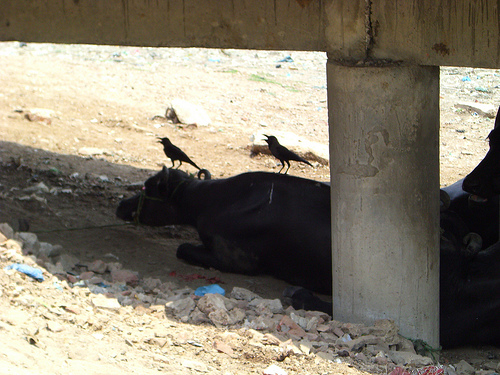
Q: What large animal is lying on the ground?
A: Cow.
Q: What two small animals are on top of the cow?
A: Black birds.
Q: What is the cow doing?
A: Lying down.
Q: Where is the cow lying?
A: Under a bridge.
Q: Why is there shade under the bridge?
A: The sun is shining.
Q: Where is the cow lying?
A: In the shade.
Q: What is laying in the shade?
A: A black cow.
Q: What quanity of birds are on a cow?
A: Two.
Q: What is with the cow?
A: Birds.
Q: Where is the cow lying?
A: On rocks.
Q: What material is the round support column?
A: Cement.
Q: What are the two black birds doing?
A: Singing.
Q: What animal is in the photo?
A: A cow.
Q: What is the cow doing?
A: Laying down.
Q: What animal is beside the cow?
A: The bird.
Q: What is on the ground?
A: Rocks.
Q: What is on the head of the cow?
A: Horns.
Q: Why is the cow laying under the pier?
A: For shade.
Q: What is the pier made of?
A: Concrete.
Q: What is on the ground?
A: Rubble.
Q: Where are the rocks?
A: On the ground.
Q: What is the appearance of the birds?
A: Sillouhettes.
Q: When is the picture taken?
A: Daytime.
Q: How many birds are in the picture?
A: Two.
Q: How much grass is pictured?
A: None.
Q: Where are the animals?
A: In the shade.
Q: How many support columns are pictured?
A: One.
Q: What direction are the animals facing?
A: Left.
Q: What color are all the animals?
A: Black.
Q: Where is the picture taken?
A: In a zoo.